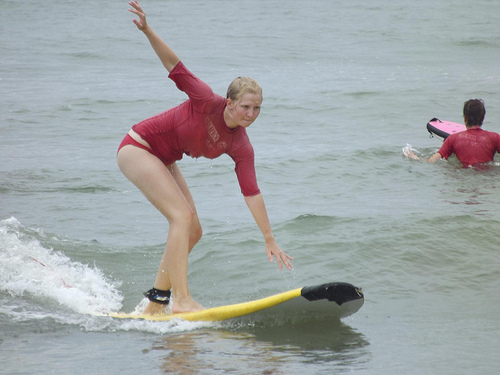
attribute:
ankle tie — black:
[140, 284, 173, 311]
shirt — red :
[118, 62, 291, 185]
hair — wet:
[226, 62, 255, 94]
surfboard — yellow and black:
[105, 282, 365, 327]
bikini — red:
[105, 135, 169, 167]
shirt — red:
[132, 61, 259, 196]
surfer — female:
[101, 2, 298, 321]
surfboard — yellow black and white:
[119, 274, 369, 330]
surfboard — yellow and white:
[63, 278, 378, 327]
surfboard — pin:
[425, 117, 468, 139]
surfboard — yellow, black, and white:
[112, 281, 364, 323]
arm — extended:
[234, 157, 296, 269]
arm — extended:
[127, 2, 207, 94]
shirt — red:
[152, 103, 210, 188]